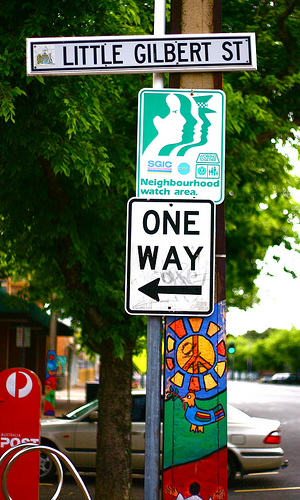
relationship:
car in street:
[47, 377, 275, 484] [42, 429, 297, 500]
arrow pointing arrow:
[134, 278, 201, 302] [138, 277, 203, 302]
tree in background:
[0, 0, 300, 500] [226, 306, 299, 403]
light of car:
[261, 424, 287, 459] [39, 373, 288, 492]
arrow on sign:
[134, 278, 201, 302] [125, 197, 215, 315]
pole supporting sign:
[144, 315, 163, 499] [125, 197, 215, 315]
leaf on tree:
[0, 0, 300, 359] [0, 0, 297, 498]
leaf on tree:
[82, 154, 90, 162] [0, 0, 297, 498]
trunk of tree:
[96, 337, 134, 497] [0, 0, 297, 498]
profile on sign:
[142, 91, 217, 156] [136, 88, 226, 203]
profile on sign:
[168, 94, 203, 157] [136, 88, 226, 203]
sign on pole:
[175, 334, 215, 373] [162, 0, 226, 497]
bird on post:
[179, 387, 227, 435] [155, 170, 235, 499]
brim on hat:
[195, 96, 210, 110] [193, 95, 215, 114]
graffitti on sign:
[128, 244, 212, 310] [125, 197, 215, 315]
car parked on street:
[39, 373, 288, 492] [40, 378, 297, 496]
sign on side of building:
[10, 322, 33, 352] [0, 290, 72, 394]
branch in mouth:
[166, 386, 186, 411] [179, 396, 187, 402]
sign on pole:
[125, 197, 215, 315] [147, 316, 159, 499]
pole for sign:
[140, 314, 166, 496] [25, 34, 255, 74]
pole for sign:
[140, 314, 166, 496] [136, 88, 226, 203]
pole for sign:
[140, 314, 166, 496] [125, 197, 215, 315]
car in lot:
[39, 373, 288, 492] [38, 466, 297, 497]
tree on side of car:
[0, 0, 297, 498] [39, 373, 288, 492]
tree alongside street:
[0, 0, 300, 500] [227, 381, 299, 497]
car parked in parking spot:
[39, 373, 288, 492] [23, 359, 299, 481]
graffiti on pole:
[169, 321, 223, 498] [162, 0, 226, 497]